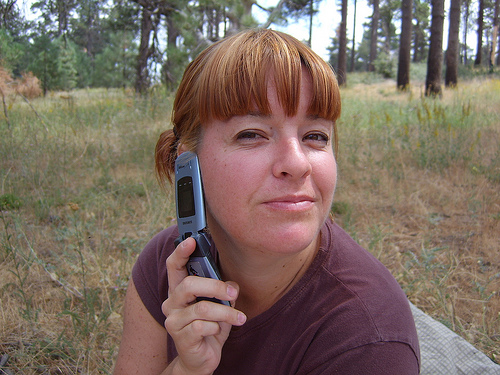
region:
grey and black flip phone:
[173, 150, 230, 303]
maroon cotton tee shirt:
[132, 220, 422, 373]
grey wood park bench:
[410, 299, 499, 374]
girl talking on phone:
[121, 29, 421, 374]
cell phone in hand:
[165, 153, 247, 368]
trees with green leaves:
[3, 0, 138, 92]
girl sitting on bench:
[108, 27, 420, 374]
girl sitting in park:
[121, 33, 421, 370]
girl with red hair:
[114, 30, 419, 374]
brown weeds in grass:
[343, 93, 499, 177]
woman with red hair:
[147, 20, 361, 280]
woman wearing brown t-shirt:
[111, 25, 399, 371]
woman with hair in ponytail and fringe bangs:
[146, 15, 342, 267]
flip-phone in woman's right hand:
[162, 130, 245, 373]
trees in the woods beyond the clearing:
[3, 2, 495, 123]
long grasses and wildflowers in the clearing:
[5, 69, 495, 356]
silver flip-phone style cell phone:
[165, 147, 237, 323]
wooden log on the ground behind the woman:
[396, 288, 497, 373]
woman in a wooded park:
[4, 0, 484, 373]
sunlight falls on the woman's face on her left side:
[178, 33, 348, 275]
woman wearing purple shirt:
[106, 15, 456, 366]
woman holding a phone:
[102, 10, 422, 370]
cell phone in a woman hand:
[141, 150, 251, 361]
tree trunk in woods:
[415, 10, 446, 113]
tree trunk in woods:
[446, 0, 461, 93]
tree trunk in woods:
[390, 3, 421, 99]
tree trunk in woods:
[335, 0, 356, 75]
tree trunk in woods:
[130, 21, 158, 91]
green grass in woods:
[23, 90, 123, 180]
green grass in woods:
[358, 109, 483, 166]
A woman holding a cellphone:
[113, 25, 419, 372]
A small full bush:
[371, 49, 398, 79]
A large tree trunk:
[420, 1, 447, 93]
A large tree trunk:
[395, 0, 417, 92]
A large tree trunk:
[444, 0, 463, 88]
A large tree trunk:
[336, 0, 351, 89]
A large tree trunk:
[131, 3, 156, 100]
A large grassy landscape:
[1, 73, 498, 372]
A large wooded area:
[5, 2, 499, 95]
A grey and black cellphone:
[172, 148, 234, 307]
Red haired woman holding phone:
[111, 23, 425, 370]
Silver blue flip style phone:
[152, 150, 249, 325]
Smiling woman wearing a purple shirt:
[116, 27, 422, 369]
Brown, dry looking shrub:
[1, 54, 48, 115]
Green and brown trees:
[5, 4, 497, 100]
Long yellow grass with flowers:
[354, 82, 490, 179]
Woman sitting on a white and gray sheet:
[113, 25, 495, 370]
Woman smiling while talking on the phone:
[113, 27, 423, 367]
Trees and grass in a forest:
[3, 5, 498, 374]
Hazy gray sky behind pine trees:
[6, 4, 498, 116]